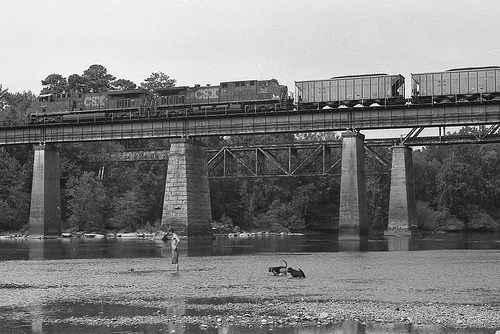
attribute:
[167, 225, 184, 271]
boy — young, present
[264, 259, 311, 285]
dogs — resting, present, black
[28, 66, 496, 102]
train — metal, long, present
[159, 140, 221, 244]
pillar — stone, large, brick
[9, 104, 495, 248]
bridge — present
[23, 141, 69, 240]
pillar — stone, brick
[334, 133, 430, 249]
pillar — brick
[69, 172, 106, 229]
bush — present